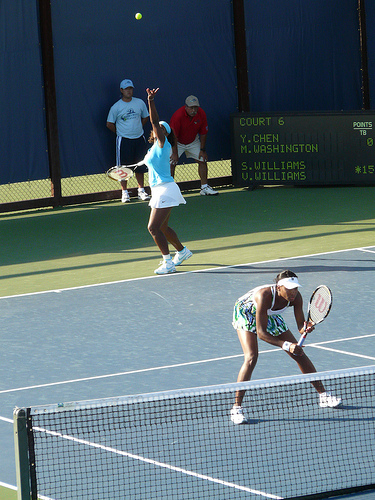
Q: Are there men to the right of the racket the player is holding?
A: Yes, there is a man to the right of the tennis racket.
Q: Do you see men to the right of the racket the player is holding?
A: Yes, there is a man to the right of the tennis racket.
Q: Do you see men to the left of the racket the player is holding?
A: No, the man is to the right of the tennis racket.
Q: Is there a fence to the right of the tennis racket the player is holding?
A: No, there is a man to the right of the tennis racket.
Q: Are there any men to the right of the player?
A: Yes, there is a man to the right of the player.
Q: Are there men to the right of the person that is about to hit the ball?
A: Yes, there is a man to the right of the player.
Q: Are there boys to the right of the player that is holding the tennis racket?
A: No, there is a man to the right of the player.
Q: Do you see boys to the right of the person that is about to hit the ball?
A: No, there is a man to the right of the player.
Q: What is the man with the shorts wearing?
A: The man is wearing a shirt.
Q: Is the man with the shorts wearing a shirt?
A: Yes, the man is wearing a shirt.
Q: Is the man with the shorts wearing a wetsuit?
A: No, the man is wearing a shirt.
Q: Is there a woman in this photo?
A: Yes, there is a woman.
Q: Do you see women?
A: Yes, there is a woman.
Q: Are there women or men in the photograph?
A: Yes, there is a woman.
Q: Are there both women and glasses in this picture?
A: No, there is a woman but no glasses.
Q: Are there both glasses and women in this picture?
A: No, there is a woman but no glasses.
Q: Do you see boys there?
A: No, there are no boys.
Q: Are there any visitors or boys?
A: No, there are no boys or visitors.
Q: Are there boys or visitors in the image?
A: No, there are no boys or visitors.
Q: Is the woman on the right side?
A: Yes, the woman is on the right of the image.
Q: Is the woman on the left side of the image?
A: No, the woman is on the right of the image.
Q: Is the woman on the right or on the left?
A: The woman is on the right of the image.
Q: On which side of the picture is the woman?
A: The woman is on the right of the image.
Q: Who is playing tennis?
A: The woman is playing tennis.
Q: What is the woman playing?
A: The woman is playing tennis.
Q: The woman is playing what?
A: The woman is playing tennis.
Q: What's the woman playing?
A: The woman is playing tennis.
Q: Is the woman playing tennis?
A: Yes, the woman is playing tennis.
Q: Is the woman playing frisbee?
A: No, the woman is playing tennis.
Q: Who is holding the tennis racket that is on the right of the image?
A: The woman is holding the tennis racket.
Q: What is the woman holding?
A: The woman is holding the tennis racket.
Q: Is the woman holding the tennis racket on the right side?
A: Yes, the woman is holding the racket.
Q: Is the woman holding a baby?
A: No, the woman is holding the racket.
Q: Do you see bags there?
A: No, there are no bags.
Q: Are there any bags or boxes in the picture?
A: No, there are no bags or boxes.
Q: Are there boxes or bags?
A: No, there are no bags or boxes.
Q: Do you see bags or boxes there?
A: No, there are no bags or boxes.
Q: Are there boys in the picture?
A: No, there are no boys.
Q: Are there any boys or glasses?
A: No, there are no boys or glasses.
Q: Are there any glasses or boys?
A: No, there are no boys or glasses.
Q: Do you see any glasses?
A: No, there are no glasses.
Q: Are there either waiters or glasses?
A: No, there are no glasses or waiters.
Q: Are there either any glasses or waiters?
A: No, there are no glasses or waiters.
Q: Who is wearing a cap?
A: The man is wearing a cap.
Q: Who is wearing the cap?
A: The man is wearing a cap.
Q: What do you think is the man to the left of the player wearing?
A: The man is wearing a cap.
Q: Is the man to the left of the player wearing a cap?
A: Yes, the man is wearing a cap.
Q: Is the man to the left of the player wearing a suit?
A: No, the man is wearing a cap.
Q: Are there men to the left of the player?
A: Yes, there is a man to the left of the player.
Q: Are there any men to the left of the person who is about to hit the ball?
A: Yes, there is a man to the left of the player.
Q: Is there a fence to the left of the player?
A: No, there is a man to the left of the player.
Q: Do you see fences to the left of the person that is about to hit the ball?
A: No, there is a man to the left of the player.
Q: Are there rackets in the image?
A: Yes, there is a racket.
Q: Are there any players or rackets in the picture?
A: Yes, there is a racket.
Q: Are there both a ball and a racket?
A: Yes, there are both a racket and a ball.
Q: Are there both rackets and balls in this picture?
A: Yes, there are both a racket and a ball.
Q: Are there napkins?
A: No, there are no napkins.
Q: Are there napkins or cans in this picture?
A: No, there are no napkins or cans.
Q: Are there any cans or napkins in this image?
A: No, there are no napkins or cans.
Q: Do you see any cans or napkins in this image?
A: No, there are no napkins or cans.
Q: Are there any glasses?
A: No, there are no glasses.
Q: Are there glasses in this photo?
A: No, there are no glasses.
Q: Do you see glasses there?
A: No, there are no glasses.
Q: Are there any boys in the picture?
A: No, there are no boys.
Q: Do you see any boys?
A: No, there are no boys.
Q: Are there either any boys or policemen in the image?
A: No, there are no boys or policemen.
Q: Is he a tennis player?
A: Yes, this is a tennis player.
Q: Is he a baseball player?
A: No, this is a tennis player.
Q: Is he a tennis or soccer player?
A: This is a tennis player.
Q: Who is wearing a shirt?
A: The player is wearing a shirt.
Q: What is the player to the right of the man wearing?
A: The player is wearing a shirt.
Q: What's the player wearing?
A: The player is wearing a shirt.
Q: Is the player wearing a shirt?
A: Yes, the player is wearing a shirt.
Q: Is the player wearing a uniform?
A: No, the player is wearing a shirt.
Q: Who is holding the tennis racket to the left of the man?
A: The player is holding the racket.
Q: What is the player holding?
A: The player is holding the racket.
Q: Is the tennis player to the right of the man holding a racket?
A: Yes, the player is holding a racket.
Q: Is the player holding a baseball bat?
A: No, the player is holding a racket.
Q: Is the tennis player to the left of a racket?
A: No, the player is to the right of a racket.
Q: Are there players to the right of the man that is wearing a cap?
A: Yes, there is a player to the right of the man.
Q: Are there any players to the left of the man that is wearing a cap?
A: No, the player is to the right of the man.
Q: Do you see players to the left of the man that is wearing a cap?
A: No, the player is to the right of the man.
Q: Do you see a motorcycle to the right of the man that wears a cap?
A: No, there is a player to the right of the man.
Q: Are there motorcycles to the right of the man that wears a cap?
A: No, there is a player to the right of the man.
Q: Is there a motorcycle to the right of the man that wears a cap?
A: No, there is a player to the right of the man.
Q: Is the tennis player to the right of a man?
A: Yes, the player is to the right of a man.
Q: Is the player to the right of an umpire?
A: No, the player is to the right of a man.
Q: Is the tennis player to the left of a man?
A: No, the player is to the right of a man.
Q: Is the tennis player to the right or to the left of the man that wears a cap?
A: The player is to the right of the man.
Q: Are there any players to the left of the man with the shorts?
A: Yes, there is a player to the left of the man.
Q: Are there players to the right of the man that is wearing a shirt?
A: No, the player is to the left of the man.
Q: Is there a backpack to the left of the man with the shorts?
A: No, there is a player to the left of the man.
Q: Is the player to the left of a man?
A: Yes, the player is to the left of a man.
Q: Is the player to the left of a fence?
A: No, the player is to the left of a man.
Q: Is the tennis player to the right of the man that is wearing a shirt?
A: No, the player is to the left of the man.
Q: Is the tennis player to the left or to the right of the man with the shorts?
A: The player is to the left of the man.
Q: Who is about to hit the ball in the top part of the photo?
A: The player is about to hit the ball.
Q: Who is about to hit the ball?
A: The player is about to hit the ball.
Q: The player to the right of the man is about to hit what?
A: The player is about to hit the ball.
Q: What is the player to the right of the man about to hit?
A: The player is about to hit the ball.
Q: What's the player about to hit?
A: The player is about to hit the ball.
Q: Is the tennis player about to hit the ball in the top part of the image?
A: Yes, the player is about to hit the ball.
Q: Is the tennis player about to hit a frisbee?
A: No, the player is about to hit the ball.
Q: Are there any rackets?
A: Yes, there is a racket.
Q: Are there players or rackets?
A: Yes, there is a racket.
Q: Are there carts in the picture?
A: No, there are no carts.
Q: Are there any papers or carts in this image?
A: No, there are no carts or papers.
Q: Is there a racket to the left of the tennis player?
A: Yes, there is a racket to the left of the player.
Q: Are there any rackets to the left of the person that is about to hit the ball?
A: Yes, there is a racket to the left of the player.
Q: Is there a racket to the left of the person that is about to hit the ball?
A: Yes, there is a racket to the left of the player.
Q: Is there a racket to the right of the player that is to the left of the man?
A: No, the racket is to the left of the player.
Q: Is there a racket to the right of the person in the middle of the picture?
A: No, the racket is to the left of the player.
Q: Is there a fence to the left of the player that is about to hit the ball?
A: No, there is a racket to the left of the player.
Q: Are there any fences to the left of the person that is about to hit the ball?
A: No, there is a racket to the left of the player.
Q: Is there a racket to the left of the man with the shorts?
A: Yes, there is a racket to the left of the man.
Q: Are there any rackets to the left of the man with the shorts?
A: Yes, there is a racket to the left of the man.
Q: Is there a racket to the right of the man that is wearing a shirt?
A: No, the racket is to the left of the man.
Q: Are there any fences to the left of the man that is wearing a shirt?
A: No, there is a racket to the left of the man.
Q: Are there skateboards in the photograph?
A: No, there are no skateboards.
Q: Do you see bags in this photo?
A: No, there are no bags.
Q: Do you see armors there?
A: No, there are no armors.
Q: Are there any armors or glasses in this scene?
A: No, there are no armors or glasses.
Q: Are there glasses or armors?
A: No, there are no armors or glasses.